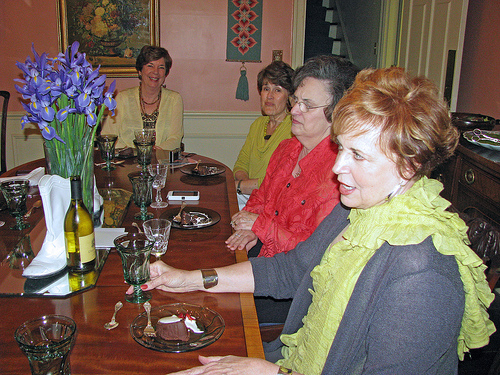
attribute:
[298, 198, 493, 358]
scarf — green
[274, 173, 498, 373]
scarf — lime green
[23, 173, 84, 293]
shoe — white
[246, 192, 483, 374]
scarf — green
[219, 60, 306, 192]
woman — wearing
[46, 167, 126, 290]
bottle — yellow